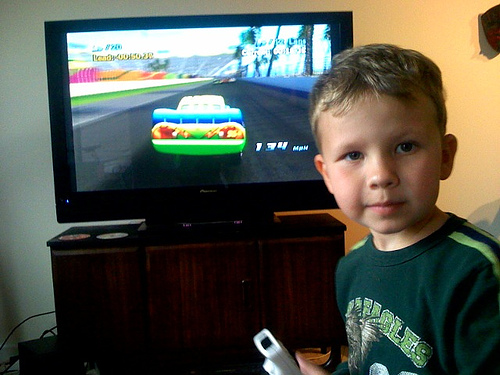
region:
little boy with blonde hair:
[295, 42, 496, 372]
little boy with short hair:
[285, 42, 496, 369]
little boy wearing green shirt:
[290, 42, 498, 373]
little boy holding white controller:
[256, 40, 498, 373]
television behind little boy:
[43, 12, 351, 225]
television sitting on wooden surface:
[44, 12, 353, 230]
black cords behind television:
[0, 318, 60, 370]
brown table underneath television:
[45, 210, 351, 369]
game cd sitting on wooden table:
[56, 233, 93, 241]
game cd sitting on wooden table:
[94, 231, 127, 241]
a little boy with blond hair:
[237, 38, 469, 374]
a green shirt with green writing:
[298, 218, 498, 373]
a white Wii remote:
[243, 317, 315, 374]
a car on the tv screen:
[121, 53, 305, 185]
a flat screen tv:
[34, 9, 398, 240]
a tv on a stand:
[33, 15, 377, 242]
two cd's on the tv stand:
[38, 221, 143, 263]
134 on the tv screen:
[245, 132, 302, 167]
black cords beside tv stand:
[1, 296, 63, 374]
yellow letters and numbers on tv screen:
[90, 47, 161, 67]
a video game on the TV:
[65, 23, 337, 183]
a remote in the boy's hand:
[254, 329, 319, 374]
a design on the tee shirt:
[344, 299, 426, 373]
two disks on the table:
[55, 231, 127, 240]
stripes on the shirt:
[451, 220, 499, 274]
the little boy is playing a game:
[261, 43, 499, 373]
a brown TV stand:
[47, 213, 344, 374]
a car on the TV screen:
[148, 94, 244, 156]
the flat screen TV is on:
[42, 10, 353, 222]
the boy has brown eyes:
[343, 140, 421, 165]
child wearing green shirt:
[278, 61, 474, 366]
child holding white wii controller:
[233, 95, 434, 374]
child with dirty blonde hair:
[304, 50, 464, 147]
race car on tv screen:
[137, 78, 266, 175]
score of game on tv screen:
[82, 40, 169, 65]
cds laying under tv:
[47, 228, 134, 247]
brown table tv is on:
[42, 214, 347, 340]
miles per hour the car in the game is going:
[247, 135, 314, 160]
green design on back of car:
[139, 116, 268, 158]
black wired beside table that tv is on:
[4, 305, 70, 370]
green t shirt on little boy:
[315, 213, 496, 325]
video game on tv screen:
[67, 30, 322, 185]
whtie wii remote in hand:
[249, 319, 298, 374]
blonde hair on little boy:
[319, 23, 401, 97]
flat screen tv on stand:
[45, 16, 347, 211]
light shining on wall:
[426, 3, 498, 129]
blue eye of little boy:
[400, 140, 425, 157]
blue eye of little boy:
[338, 148, 368, 167]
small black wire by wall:
[2, 297, 48, 324]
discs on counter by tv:
[65, 227, 142, 248]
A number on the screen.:
[251, 141, 266, 152]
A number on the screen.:
[264, 140, 275, 151]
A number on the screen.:
[278, 137, 288, 150]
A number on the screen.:
[148, 51, 155, 60]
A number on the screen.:
[141, 52, 148, 60]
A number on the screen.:
[134, 50, 139, 61]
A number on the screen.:
[130, 53, 137, 60]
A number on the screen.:
[123, 52, 132, 60]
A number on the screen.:
[118, 52, 120, 59]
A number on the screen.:
[271, 38, 282, 42]